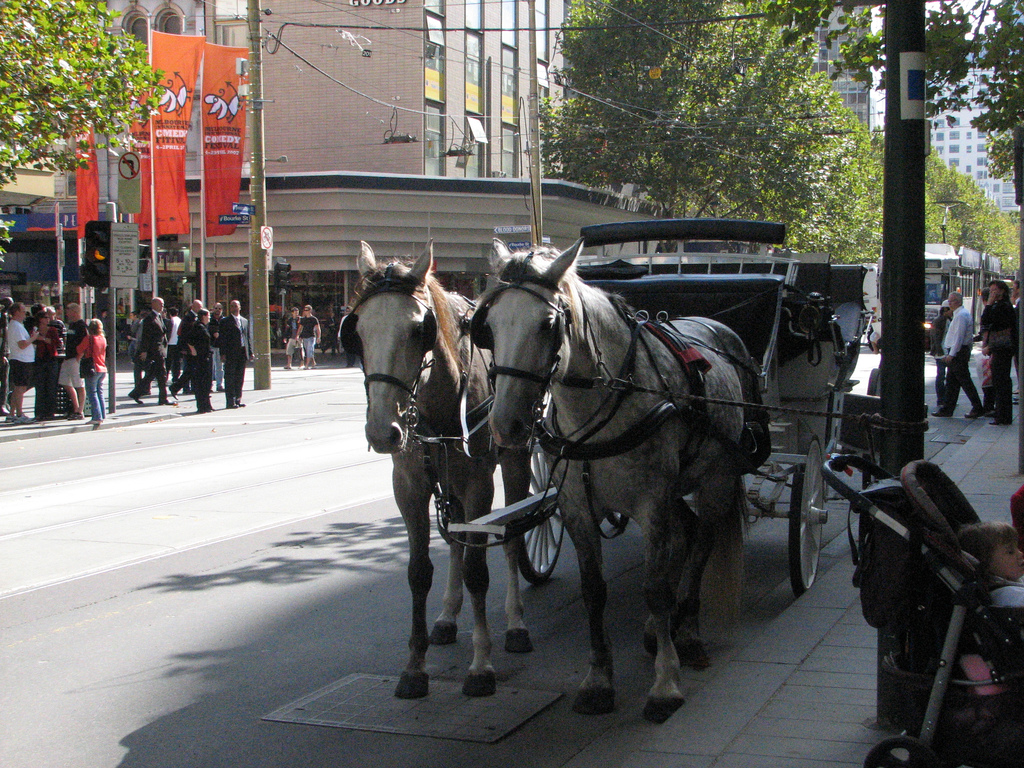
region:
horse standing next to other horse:
[335, 234, 763, 729]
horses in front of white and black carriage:
[331, 212, 879, 725]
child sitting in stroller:
[818, 448, 1022, 766]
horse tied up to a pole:
[464, 31, 935, 717]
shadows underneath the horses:
[108, 236, 779, 767]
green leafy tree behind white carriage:
[505, 3, 878, 601]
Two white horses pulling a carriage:
[337, 233, 770, 746]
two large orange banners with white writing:
[119, 10, 256, 242]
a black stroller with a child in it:
[814, 436, 1023, 766]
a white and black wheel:
[773, 442, 857, 595]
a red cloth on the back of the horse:
[640, 315, 730, 385]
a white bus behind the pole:
[876, 240, 974, 352]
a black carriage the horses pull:
[555, 186, 873, 471]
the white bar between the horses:
[438, 483, 553, 559]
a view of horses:
[281, 224, 627, 462]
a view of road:
[186, 613, 273, 658]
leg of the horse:
[350, 489, 541, 706]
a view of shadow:
[167, 569, 365, 750]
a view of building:
[274, 25, 628, 260]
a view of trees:
[588, 48, 864, 233]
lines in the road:
[717, 654, 810, 728]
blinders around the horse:
[309, 296, 471, 345]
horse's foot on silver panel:
[268, 632, 586, 751]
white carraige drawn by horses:
[319, 171, 857, 732]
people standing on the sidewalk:
[14, 279, 275, 390]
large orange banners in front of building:
[76, 2, 292, 253]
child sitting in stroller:
[959, 509, 1021, 571]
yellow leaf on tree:
[628, 49, 685, 97]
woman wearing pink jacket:
[74, 313, 123, 381]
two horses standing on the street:
[332, 246, 775, 725]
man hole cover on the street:
[276, 661, 574, 747]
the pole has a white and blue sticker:
[882, 9, 936, 213]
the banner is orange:
[137, 29, 196, 236]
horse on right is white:
[459, 230, 779, 740]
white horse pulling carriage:
[462, 236, 780, 736]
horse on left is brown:
[333, 235, 543, 708]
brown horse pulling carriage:
[327, 233, 550, 714]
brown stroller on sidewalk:
[817, 438, 1020, 765]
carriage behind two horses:
[504, 200, 866, 627]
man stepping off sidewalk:
[930, 283, 989, 429]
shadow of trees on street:
[130, 500, 457, 706]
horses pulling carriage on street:
[343, 195, 878, 740]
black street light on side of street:
[71, 212, 135, 416]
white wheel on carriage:
[779, 423, 837, 604]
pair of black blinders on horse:
[460, 295, 569, 359]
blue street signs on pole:
[219, 193, 271, 222]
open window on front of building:
[457, 105, 489, 162]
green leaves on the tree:
[741, 125, 777, 154]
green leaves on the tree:
[64, 3, 144, 112]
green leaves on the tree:
[836, 150, 857, 218]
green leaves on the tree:
[971, 194, 1022, 255]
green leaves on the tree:
[1012, 44, 1022, 65]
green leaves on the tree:
[771, 160, 813, 203]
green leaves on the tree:
[806, 125, 871, 256]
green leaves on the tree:
[686, 84, 795, 247]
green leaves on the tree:
[696, 59, 732, 117]